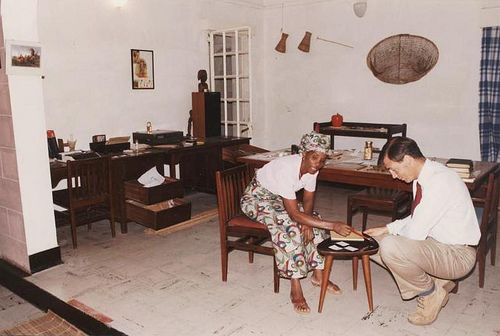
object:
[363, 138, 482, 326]
man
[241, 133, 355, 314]
woman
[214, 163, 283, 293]
chair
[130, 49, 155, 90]
image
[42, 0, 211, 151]
wall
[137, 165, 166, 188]
paper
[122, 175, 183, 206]
drawer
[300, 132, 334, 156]
wrap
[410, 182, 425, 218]
tie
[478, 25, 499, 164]
curtain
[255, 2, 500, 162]
wall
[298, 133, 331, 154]
bonnet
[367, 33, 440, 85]
basket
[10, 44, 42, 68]
picture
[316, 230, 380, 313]
stool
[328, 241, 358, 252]
papers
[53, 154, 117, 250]
chair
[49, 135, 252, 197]
desk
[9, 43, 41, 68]
photo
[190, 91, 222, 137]
speaker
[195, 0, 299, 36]
corner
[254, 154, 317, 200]
shirt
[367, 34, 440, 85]
fan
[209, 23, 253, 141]
door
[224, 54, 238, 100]
windows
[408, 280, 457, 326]
boots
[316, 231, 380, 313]
table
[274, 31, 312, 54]
objects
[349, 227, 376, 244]
pencil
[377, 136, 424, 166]
hair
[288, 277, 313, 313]
feet